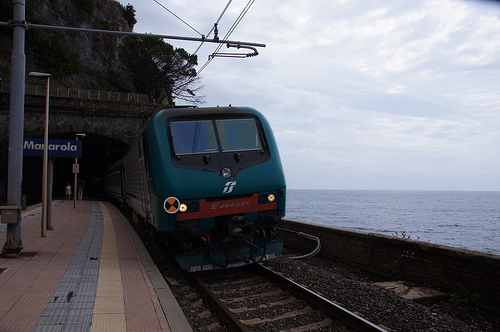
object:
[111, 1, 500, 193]
sky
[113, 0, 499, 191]
clouds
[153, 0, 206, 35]
wires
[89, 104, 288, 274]
train